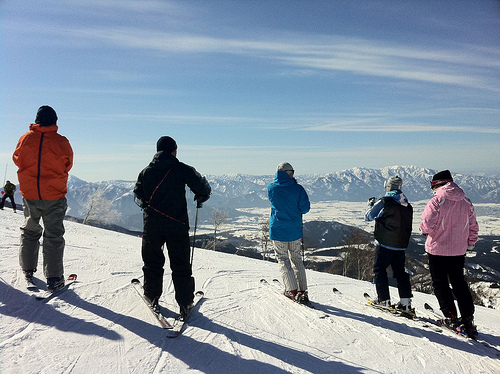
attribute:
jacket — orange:
[10, 120, 73, 202]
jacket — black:
[132, 150, 211, 225]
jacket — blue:
[262, 167, 311, 242]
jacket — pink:
[418, 188, 485, 275]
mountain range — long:
[90, 124, 495, 220]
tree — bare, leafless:
[201, 211, 233, 258]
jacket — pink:
[423, 195, 479, 258]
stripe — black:
[25, 133, 54, 193]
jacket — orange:
[7, 115, 81, 227]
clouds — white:
[239, 26, 493, 98]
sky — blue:
[56, 10, 468, 197]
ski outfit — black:
[130, 157, 226, 291]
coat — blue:
[257, 163, 313, 244]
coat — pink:
[415, 179, 483, 261]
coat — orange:
[9, 124, 73, 204]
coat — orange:
[7, 121, 77, 203]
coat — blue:
[262, 170, 316, 246]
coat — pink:
[422, 182, 482, 265]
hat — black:
[153, 133, 179, 157]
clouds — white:
[121, 26, 456, 93]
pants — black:
[422, 252, 482, 332]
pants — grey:
[13, 197, 69, 283]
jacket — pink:
[419, 181, 486, 260]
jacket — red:
[10, 118, 81, 207]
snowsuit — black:
[129, 150, 211, 305]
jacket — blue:
[265, 169, 316, 239]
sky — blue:
[3, 1, 499, 194]